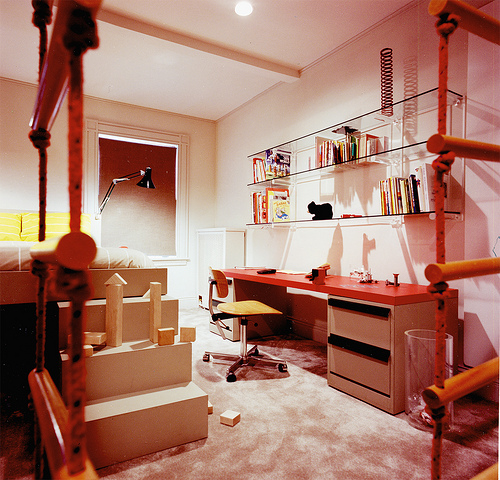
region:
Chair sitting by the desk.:
[186, 258, 321, 435]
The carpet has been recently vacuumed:
[267, 412, 387, 477]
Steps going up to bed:
[60, 247, 222, 478]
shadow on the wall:
[347, 219, 424, 317]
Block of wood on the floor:
[206, 402, 263, 430]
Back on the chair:
[196, 258, 249, 297]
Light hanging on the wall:
[98, 135, 180, 241]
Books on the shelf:
[221, 145, 498, 272]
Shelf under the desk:
[317, 292, 411, 394]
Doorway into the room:
[79, 117, 198, 227]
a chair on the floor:
[212, 275, 244, 324]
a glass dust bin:
[411, 332, 421, 406]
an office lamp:
[138, 168, 156, 189]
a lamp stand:
[106, 178, 113, 207]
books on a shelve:
[388, 174, 417, 199]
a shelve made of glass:
[286, 135, 310, 147]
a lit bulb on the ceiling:
[236, 1, 252, 13]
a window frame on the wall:
[168, 137, 188, 204]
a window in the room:
[105, 141, 136, 172]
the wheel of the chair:
[227, 370, 237, 383]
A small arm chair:
[206, 269, 293, 392]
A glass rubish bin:
[397, 329, 457, 450]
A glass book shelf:
[374, 170, 440, 216]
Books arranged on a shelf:
[311, 116, 378, 161]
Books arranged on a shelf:
[247, 187, 300, 226]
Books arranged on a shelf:
[244, 141, 294, 174]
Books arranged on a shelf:
[367, 170, 461, 209]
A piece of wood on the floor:
[217, 406, 251, 430]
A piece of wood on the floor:
[201, 394, 218, 415]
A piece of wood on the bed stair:
[144, 321, 181, 347]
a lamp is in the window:
[80, 110, 307, 326]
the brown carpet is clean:
[263, 403, 353, 476]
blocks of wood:
[90, 273, 292, 395]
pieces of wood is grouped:
[92, 268, 274, 366]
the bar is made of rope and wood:
[22, 220, 159, 400]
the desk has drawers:
[206, 250, 462, 411]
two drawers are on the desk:
[322, 275, 474, 479]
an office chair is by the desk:
[200, 256, 327, 401]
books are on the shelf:
[245, 128, 312, 240]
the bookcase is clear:
[276, 133, 350, 280]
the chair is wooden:
[206, 266, 297, 378]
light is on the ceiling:
[225, 2, 265, 18]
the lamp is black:
[123, 165, 164, 192]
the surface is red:
[274, 257, 421, 305]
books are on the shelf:
[307, 130, 378, 163]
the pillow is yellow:
[21, 214, 109, 234]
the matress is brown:
[111, 245, 164, 268]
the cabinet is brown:
[321, 305, 395, 404]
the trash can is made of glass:
[406, 323, 465, 435]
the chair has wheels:
[199, 278, 286, 386]